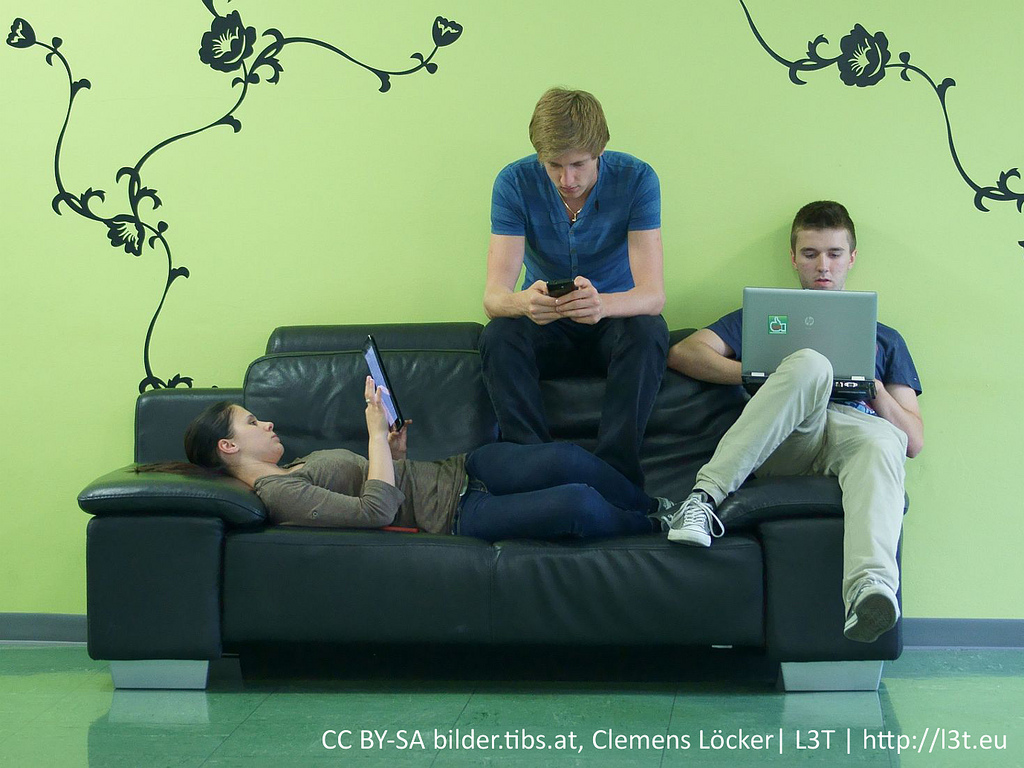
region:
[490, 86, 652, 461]
Playing on a smart phone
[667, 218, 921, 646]
Playing on a lap top computor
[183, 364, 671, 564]
Laying on the couch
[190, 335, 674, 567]
Playing on a tablet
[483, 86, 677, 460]
sitting on the back of the couch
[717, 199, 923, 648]
Sitting on the arm of the couch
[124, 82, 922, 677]
Three people playing with technology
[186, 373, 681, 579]
Adolescent holding a tablet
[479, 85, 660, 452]
Young man with blue stripped shirt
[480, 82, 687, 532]
Young man sitting on top of a couch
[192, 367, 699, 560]
Young woman laying on a couch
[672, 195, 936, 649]
Young man sitting on the arm rest of a couch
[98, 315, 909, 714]
Black leather couch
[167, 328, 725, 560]
Young woman holding a tablet device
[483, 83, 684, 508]
Young man holding a cell phone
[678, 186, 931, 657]
Young man using a laptop computer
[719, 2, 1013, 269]
Vine and flower decal painted on green wall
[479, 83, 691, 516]
Man wearing blue shirt and jeans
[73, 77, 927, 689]
young people relaxing on couch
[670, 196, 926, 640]
man on laptop computer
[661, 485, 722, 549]
gray tennis shoe on man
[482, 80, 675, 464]
man in blue shirt texting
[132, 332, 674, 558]
woman laying on couch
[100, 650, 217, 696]
silver foot of couch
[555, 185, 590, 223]
gold chain on man's neck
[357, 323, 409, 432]
black tablet held by woman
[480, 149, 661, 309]
blue t-shirt on man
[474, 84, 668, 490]
young man in blue shirt using phone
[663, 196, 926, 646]
young man in blue shirt interacting with laptop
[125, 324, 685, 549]
Young woman laying down and using tablet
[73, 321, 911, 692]
large black leather couch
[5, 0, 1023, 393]
scrolling black floral design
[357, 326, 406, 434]
black touch-screen tablet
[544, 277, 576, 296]
black smart phone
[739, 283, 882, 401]
silver lap-top computer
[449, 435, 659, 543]
dark blue denim trousers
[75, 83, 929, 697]
Three young people on the sofa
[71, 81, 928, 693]
Three young people on their gadget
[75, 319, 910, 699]
Black leather sofa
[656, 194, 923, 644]
Young man in brown pants looking at his laptop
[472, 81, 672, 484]
Young man in blue shirt looking at his phone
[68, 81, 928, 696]
Two young men and woman on the sofa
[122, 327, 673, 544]
Young woman on the sofa holding a tablet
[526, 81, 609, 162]
Hair is brown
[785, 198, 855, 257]
Hair is short and brown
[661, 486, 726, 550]
Show has a white shoelace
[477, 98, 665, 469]
A person is sitting down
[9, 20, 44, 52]
A flower on the wall.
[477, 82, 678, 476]
man sitting on top of couch with an electronical device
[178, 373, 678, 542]
woman laying on couch looking at a tablet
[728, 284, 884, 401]
laptop the man is using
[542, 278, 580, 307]
electronical device the man is using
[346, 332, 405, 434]
tablet the woman is using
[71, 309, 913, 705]
couch that all of the people are on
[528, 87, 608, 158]
blond hair of the man on back of couch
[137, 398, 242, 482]
dark hair of the woman laying on the couch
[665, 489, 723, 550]
tennis shoe of the man sitting on arm of couch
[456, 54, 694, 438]
a person the couch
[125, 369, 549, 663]
a person the couch